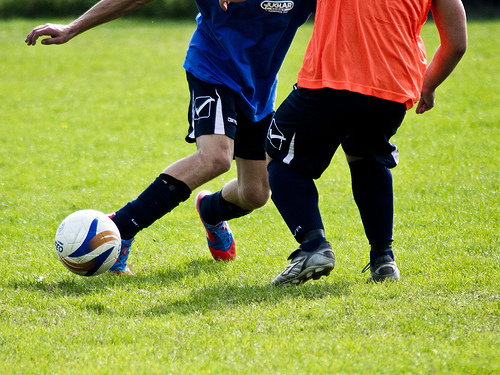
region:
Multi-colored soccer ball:
[53, 205, 126, 279]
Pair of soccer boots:
[267, 243, 407, 292]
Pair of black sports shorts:
[262, 79, 407, 172]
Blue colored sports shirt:
[181, 0, 316, 120]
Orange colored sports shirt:
[292, 0, 436, 110]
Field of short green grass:
[0, 0, 498, 374]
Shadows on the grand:
[2, 253, 355, 330]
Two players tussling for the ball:
[21, 1, 473, 292]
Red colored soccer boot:
[195, 190, 237, 266]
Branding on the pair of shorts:
[186, 89, 220, 129]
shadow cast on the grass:
[169, 251, 274, 313]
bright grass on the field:
[429, 205, 474, 294]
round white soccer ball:
[31, 203, 123, 270]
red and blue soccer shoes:
[190, 215, 246, 260]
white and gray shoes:
[269, 245, 349, 297]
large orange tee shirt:
[297, 10, 439, 86]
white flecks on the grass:
[27, 298, 107, 320]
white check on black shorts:
[254, 118, 294, 153]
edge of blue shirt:
[184, 73, 279, 105]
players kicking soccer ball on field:
[4, 13, 478, 267]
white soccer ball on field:
[25, 198, 151, 266]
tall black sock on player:
[120, 157, 175, 248]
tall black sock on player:
[204, 191, 244, 226]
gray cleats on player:
[272, 249, 348, 291]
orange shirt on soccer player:
[327, 16, 437, 112]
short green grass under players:
[152, 262, 355, 354]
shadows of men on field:
[59, 270, 175, 347]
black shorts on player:
[177, 80, 285, 147]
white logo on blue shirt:
[241, 4, 303, 30]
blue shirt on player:
[179, 30, 284, 122]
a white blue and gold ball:
[36, 196, 154, 281]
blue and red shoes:
[186, 196, 253, 270]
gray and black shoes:
[254, 245, 354, 294]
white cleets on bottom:
[277, 265, 336, 294]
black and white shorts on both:
[160, 62, 414, 180]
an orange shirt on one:
[289, 6, 441, 127]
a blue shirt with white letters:
[171, 2, 313, 119]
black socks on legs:
[90, 155, 202, 264]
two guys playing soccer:
[38, 1, 478, 288]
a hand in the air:
[19, 21, 111, 77]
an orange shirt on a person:
[289, 0, 436, 107]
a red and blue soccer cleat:
[194, 191, 237, 261]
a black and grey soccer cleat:
[268, 240, 339, 287]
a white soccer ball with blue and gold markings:
[52, 208, 121, 282]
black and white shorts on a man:
[181, 65, 273, 166]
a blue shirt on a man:
[182, 1, 316, 120]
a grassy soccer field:
[2, 17, 497, 373]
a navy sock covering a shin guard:
[266, 159, 330, 243]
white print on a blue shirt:
[258, 0, 296, 15]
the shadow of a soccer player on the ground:
[90, 269, 353, 326]